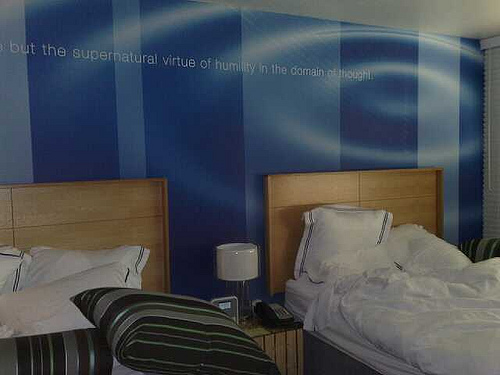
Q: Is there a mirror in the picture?
A: No, there are no mirrors.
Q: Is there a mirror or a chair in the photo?
A: No, there are no mirrors or chairs.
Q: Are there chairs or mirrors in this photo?
A: No, there are no mirrors or chairs.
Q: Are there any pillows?
A: Yes, there is a pillow.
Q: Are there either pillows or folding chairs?
A: Yes, there is a pillow.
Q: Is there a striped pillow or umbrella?
A: Yes, there is a striped pillow.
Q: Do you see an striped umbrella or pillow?
A: Yes, there is a striped pillow.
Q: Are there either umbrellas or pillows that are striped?
A: Yes, the pillow is striped.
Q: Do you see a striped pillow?
A: Yes, there is a striped pillow.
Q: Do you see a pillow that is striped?
A: Yes, there is a pillow that is striped.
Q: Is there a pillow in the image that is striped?
A: Yes, there is a pillow that is striped.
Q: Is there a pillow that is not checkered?
A: Yes, there is a striped pillow.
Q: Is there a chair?
A: No, there are no chairs.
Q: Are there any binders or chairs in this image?
A: No, there are no chairs or binders.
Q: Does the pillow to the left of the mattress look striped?
A: Yes, the pillow is striped.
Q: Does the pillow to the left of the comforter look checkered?
A: No, the pillow is striped.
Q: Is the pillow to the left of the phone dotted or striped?
A: The pillow is striped.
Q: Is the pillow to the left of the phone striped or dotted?
A: The pillow is striped.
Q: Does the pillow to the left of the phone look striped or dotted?
A: The pillow is striped.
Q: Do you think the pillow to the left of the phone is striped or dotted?
A: The pillow is striped.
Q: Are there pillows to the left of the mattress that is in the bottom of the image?
A: Yes, there is a pillow to the left of the mattress.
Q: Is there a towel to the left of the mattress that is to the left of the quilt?
A: No, there is a pillow to the left of the mattress.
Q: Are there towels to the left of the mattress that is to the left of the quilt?
A: No, there is a pillow to the left of the mattress.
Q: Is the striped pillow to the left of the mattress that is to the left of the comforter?
A: Yes, the pillow is to the left of the mattress.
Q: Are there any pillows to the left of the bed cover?
A: Yes, there is a pillow to the left of the bed cover.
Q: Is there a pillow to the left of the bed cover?
A: Yes, there is a pillow to the left of the bed cover.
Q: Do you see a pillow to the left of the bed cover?
A: Yes, there is a pillow to the left of the bed cover.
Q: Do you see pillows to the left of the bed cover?
A: Yes, there is a pillow to the left of the bed cover.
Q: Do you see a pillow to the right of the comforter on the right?
A: No, the pillow is to the left of the quilt.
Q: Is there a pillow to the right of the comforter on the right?
A: No, the pillow is to the left of the quilt.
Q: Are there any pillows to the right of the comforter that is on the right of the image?
A: No, the pillow is to the left of the quilt.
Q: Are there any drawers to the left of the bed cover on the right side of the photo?
A: No, there is a pillow to the left of the bed cover.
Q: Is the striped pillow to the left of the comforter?
A: Yes, the pillow is to the left of the comforter.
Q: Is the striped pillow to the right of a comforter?
A: No, the pillow is to the left of a comforter.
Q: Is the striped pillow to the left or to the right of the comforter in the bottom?
A: The pillow is to the left of the comforter.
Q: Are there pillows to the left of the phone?
A: Yes, there is a pillow to the left of the phone.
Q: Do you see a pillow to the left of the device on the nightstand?
A: Yes, there is a pillow to the left of the phone.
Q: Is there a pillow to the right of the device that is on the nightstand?
A: No, the pillow is to the left of the phone.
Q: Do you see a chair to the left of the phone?
A: No, there is a pillow to the left of the phone.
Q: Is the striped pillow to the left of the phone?
A: Yes, the pillow is to the left of the phone.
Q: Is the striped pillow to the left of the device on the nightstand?
A: Yes, the pillow is to the left of the phone.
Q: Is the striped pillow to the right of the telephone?
A: No, the pillow is to the left of the telephone.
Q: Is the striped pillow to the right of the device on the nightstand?
A: No, the pillow is to the left of the telephone.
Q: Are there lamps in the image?
A: Yes, there is a lamp.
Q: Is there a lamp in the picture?
A: Yes, there is a lamp.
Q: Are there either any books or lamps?
A: Yes, there is a lamp.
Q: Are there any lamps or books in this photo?
A: Yes, there is a lamp.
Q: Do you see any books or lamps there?
A: Yes, there is a lamp.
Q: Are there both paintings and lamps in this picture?
A: No, there is a lamp but no paintings.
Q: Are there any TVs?
A: No, there are no tvs.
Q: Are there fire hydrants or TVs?
A: No, there are no TVs or fire hydrants.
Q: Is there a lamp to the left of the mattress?
A: Yes, there is a lamp to the left of the mattress.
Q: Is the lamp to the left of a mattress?
A: Yes, the lamp is to the left of a mattress.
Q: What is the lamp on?
A: The lamp is on the nightstand.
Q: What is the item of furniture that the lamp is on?
A: The piece of furniture is a nightstand.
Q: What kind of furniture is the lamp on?
A: The lamp is on the nightstand.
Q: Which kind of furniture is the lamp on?
A: The lamp is on the nightstand.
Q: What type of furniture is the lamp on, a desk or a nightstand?
A: The lamp is on a nightstand.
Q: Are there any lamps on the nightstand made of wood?
A: Yes, there is a lamp on the nightstand.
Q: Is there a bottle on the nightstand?
A: No, there is a lamp on the nightstand.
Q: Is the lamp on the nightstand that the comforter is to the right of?
A: Yes, the lamp is on the nightstand.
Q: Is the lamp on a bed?
A: No, the lamp is on the nightstand.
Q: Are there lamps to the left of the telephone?
A: Yes, there is a lamp to the left of the telephone.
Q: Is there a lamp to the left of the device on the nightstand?
A: Yes, there is a lamp to the left of the telephone.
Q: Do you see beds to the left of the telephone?
A: No, there is a lamp to the left of the telephone.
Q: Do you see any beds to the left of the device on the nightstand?
A: No, there is a lamp to the left of the telephone.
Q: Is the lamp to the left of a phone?
A: Yes, the lamp is to the left of a phone.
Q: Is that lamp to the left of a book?
A: No, the lamp is to the left of a phone.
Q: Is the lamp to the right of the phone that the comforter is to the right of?
A: No, the lamp is to the left of the telephone.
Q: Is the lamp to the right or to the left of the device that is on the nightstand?
A: The lamp is to the left of the phone.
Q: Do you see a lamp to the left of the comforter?
A: Yes, there is a lamp to the left of the comforter.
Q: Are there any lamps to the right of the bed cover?
A: No, the lamp is to the left of the bed cover.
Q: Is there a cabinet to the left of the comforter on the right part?
A: No, there is a lamp to the left of the comforter.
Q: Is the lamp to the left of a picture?
A: No, the lamp is to the left of the quilt.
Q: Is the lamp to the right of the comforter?
A: No, the lamp is to the left of the comforter.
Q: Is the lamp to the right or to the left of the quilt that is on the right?
A: The lamp is to the left of the quilt.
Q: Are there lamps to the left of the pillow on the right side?
A: Yes, there is a lamp to the left of the pillow.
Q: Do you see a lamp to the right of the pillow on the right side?
A: No, the lamp is to the left of the pillow.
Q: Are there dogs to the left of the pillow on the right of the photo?
A: No, there is a lamp to the left of the pillow.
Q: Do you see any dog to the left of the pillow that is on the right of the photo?
A: No, there is a lamp to the left of the pillow.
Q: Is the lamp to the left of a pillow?
A: Yes, the lamp is to the left of a pillow.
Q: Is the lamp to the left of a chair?
A: No, the lamp is to the left of a pillow.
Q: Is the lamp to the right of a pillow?
A: No, the lamp is to the left of a pillow.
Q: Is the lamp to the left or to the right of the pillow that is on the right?
A: The lamp is to the left of the pillow.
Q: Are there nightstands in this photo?
A: Yes, there is a nightstand.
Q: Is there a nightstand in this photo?
A: Yes, there is a nightstand.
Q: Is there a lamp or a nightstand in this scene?
A: Yes, there is a nightstand.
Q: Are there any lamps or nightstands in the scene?
A: Yes, there is a nightstand.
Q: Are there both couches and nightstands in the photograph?
A: No, there is a nightstand but no couches.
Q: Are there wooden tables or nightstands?
A: Yes, there is a wood nightstand.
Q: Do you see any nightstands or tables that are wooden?
A: Yes, the nightstand is wooden.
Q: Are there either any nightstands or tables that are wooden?
A: Yes, the nightstand is wooden.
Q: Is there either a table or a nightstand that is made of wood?
A: Yes, the nightstand is made of wood.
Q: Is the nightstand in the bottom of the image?
A: Yes, the nightstand is in the bottom of the image.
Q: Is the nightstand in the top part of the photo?
A: No, the nightstand is in the bottom of the image.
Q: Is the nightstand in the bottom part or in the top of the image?
A: The nightstand is in the bottom of the image.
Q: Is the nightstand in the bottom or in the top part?
A: The nightstand is in the bottom of the image.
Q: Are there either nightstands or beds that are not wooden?
A: No, there is a nightstand but it is wooden.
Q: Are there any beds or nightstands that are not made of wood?
A: No, there is a nightstand but it is made of wood.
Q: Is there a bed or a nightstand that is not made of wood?
A: No, there is a nightstand but it is made of wood.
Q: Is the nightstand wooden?
A: Yes, the nightstand is wooden.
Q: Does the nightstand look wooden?
A: Yes, the nightstand is wooden.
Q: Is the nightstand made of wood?
A: Yes, the nightstand is made of wood.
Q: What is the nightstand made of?
A: The nightstand is made of wood.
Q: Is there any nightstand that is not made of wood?
A: No, there is a nightstand but it is made of wood.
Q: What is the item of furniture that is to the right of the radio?
A: The piece of furniture is a nightstand.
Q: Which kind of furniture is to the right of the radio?
A: The piece of furniture is a nightstand.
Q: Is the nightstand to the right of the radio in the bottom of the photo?
A: Yes, the nightstand is to the right of the radio.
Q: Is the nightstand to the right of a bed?
A: No, the nightstand is to the right of the radio.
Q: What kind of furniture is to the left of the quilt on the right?
A: The piece of furniture is a nightstand.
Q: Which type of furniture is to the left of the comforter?
A: The piece of furniture is a nightstand.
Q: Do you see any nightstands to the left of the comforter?
A: Yes, there is a nightstand to the left of the comforter.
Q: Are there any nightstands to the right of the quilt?
A: No, the nightstand is to the left of the quilt.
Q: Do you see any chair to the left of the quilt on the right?
A: No, there is a nightstand to the left of the bed cover.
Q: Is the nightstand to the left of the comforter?
A: Yes, the nightstand is to the left of the comforter.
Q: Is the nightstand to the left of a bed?
A: No, the nightstand is to the left of the comforter.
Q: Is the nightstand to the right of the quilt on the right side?
A: No, the nightstand is to the left of the bed cover.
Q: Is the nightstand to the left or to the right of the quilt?
A: The nightstand is to the left of the quilt.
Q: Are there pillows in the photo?
A: Yes, there is a pillow.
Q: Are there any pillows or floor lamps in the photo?
A: Yes, there is a pillow.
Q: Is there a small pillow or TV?
A: Yes, there is a small pillow.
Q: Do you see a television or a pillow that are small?
A: Yes, the pillow is small.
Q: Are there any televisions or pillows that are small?
A: Yes, the pillow is small.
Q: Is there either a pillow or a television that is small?
A: Yes, the pillow is small.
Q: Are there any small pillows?
A: Yes, there is a small pillow.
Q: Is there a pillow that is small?
A: Yes, there is a pillow that is small.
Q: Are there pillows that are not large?
A: Yes, there is a small pillow.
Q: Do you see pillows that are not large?
A: Yes, there is a small pillow.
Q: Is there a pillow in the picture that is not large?
A: Yes, there is a small pillow.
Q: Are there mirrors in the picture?
A: No, there are no mirrors.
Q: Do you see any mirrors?
A: No, there are no mirrors.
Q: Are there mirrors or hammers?
A: No, there are no mirrors or hammers.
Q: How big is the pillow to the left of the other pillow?
A: The pillow is small.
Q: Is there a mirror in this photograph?
A: No, there are no mirrors.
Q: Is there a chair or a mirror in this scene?
A: No, there are no mirrors or chairs.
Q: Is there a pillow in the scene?
A: Yes, there is a pillow.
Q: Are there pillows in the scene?
A: Yes, there is a pillow.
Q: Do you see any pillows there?
A: Yes, there is a pillow.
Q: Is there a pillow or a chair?
A: Yes, there is a pillow.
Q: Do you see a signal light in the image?
A: No, there are no traffic lights.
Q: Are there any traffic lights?
A: No, there are no traffic lights.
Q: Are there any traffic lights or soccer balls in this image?
A: No, there are no traffic lights or soccer balls.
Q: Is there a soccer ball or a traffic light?
A: No, there are no traffic lights or soccer balls.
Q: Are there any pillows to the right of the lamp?
A: Yes, there is a pillow to the right of the lamp.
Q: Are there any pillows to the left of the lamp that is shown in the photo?
A: No, the pillow is to the right of the lamp.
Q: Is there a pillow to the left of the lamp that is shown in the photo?
A: No, the pillow is to the right of the lamp.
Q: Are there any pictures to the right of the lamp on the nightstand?
A: No, there is a pillow to the right of the lamp.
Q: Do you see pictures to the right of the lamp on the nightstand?
A: No, there is a pillow to the right of the lamp.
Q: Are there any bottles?
A: No, there are no bottles.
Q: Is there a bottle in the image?
A: No, there are no bottles.